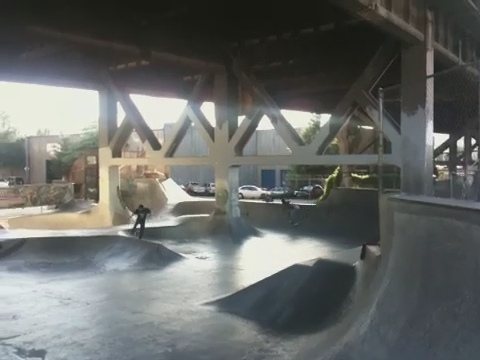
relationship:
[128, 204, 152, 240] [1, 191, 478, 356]
guy at park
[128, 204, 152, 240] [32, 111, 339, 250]
guy at park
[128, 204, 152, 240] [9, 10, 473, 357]
guy at park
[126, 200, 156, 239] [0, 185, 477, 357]
guy at skate park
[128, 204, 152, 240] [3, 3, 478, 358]
guy at skate park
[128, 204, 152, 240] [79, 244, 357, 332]
guy at skate park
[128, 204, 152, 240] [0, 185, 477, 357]
guy in skate park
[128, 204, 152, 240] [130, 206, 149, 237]
guy in clothing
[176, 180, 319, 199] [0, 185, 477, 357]
cars parked behind skate park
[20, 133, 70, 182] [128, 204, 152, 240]
building behind guy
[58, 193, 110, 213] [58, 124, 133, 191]
grass near tree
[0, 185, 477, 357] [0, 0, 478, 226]
skate park under structure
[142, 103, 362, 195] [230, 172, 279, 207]
building by car